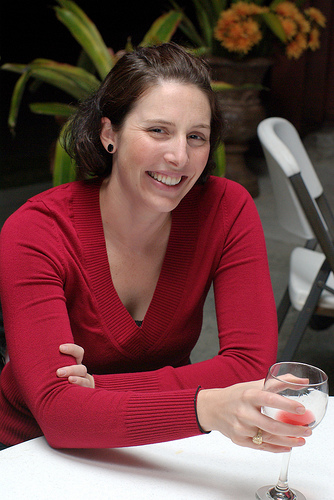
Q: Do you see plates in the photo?
A: No, there are no plates.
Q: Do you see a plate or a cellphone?
A: No, there are no plates or cell phones.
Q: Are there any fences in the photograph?
A: No, there are no fences.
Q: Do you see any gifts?
A: No, there are no gifts.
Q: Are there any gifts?
A: No, there are no gifts.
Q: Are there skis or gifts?
A: No, there are no gifts or skis.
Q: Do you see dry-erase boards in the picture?
A: No, there are no dry-erase boards.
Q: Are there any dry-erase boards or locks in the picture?
A: No, there are no dry-erase boards or locks.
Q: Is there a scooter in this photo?
A: No, there are no scooters.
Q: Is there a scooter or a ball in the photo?
A: No, there are no scooters or balls.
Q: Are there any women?
A: Yes, there is a woman.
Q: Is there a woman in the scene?
A: Yes, there is a woman.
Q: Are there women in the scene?
A: Yes, there is a woman.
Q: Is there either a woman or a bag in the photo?
A: Yes, there is a woman.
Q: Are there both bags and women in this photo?
A: No, there is a woman but no bags.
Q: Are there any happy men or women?
A: Yes, there is a happy woman.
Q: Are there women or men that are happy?
A: Yes, the woman is happy.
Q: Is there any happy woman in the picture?
A: Yes, there is a happy woman.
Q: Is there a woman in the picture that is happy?
A: Yes, there is a woman that is happy.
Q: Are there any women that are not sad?
A: Yes, there is a happy woman.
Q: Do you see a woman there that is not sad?
A: Yes, there is a happy woman.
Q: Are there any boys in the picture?
A: No, there are no boys.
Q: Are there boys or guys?
A: No, there are no boys or guys.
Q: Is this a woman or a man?
A: This is a woman.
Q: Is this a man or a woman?
A: This is a woman.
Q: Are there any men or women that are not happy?
A: No, there is a woman but she is happy.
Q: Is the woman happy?
A: Yes, the woman is happy.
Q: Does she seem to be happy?
A: Yes, the woman is happy.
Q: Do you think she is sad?
A: No, the woman is happy.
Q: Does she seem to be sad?
A: No, the woman is happy.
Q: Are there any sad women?
A: No, there is a woman but she is happy.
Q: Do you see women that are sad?
A: No, there is a woman but she is happy.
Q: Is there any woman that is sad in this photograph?
A: No, there is a woman but she is happy.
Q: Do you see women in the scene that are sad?
A: No, there is a woman but she is happy.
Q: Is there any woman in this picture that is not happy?
A: No, there is a woman but she is happy.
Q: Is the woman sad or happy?
A: The woman is happy.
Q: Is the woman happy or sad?
A: The woman is happy.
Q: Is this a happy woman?
A: Yes, this is a happy woman.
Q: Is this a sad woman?
A: No, this is a happy woman.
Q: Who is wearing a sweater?
A: The woman is wearing a sweater.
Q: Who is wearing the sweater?
A: The woman is wearing a sweater.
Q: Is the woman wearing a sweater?
A: Yes, the woman is wearing a sweater.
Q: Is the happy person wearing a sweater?
A: Yes, the woman is wearing a sweater.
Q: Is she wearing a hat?
A: No, the woman is wearing a sweater.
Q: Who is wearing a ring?
A: The woman is wearing a ring.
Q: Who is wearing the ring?
A: The woman is wearing a ring.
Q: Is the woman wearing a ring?
A: Yes, the woman is wearing a ring.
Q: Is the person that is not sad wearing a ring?
A: Yes, the woman is wearing a ring.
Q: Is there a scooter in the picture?
A: No, there are no scooters.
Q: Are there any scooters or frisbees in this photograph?
A: No, there are no scooters or frisbees.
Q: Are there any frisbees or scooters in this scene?
A: No, there are no scooters or frisbees.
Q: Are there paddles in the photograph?
A: No, there are no paddles.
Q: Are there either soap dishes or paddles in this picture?
A: No, there are no paddles or soap dishes.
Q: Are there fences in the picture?
A: No, there are no fences.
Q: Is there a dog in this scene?
A: No, there are no dogs.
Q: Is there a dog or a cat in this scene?
A: No, there are no dogs or cats.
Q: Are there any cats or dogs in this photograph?
A: No, there are no dogs or cats.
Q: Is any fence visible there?
A: No, there are no fences.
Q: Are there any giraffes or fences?
A: No, there are no fences or giraffes.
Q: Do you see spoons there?
A: No, there are no spoons.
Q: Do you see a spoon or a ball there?
A: No, there are no spoons or balls.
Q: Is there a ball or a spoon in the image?
A: No, there are no spoons or balls.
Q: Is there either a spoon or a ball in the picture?
A: No, there are no spoons or balls.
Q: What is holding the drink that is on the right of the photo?
A: The glass is holding the wine.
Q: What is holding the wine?
A: The glass is holding the wine.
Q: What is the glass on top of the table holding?
A: The glass is holding the wine.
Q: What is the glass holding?
A: The glass is holding the wine.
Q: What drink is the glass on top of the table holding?
A: The glass is holding the wine.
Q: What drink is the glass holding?
A: The glass is holding the wine.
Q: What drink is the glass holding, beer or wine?
A: The glass is holding wine.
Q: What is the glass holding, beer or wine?
A: The glass is holding wine.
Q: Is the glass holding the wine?
A: Yes, the glass is holding the wine.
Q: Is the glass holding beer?
A: No, the glass is holding the wine.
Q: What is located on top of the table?
A: The glass is on top of the table.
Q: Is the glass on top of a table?
A: Yes, the glass is on top of a table.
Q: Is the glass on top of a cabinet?
A: No, the glass is on top of a table.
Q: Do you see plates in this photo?
A: No, there are no plates.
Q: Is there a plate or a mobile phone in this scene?
A: No, there are no plates or cell phones.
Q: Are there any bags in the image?
A: No, there are no bags.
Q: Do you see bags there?
A: No, there are no bags.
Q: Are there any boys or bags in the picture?
A: No, there are no bags or boys.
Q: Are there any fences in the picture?
A: No, there are no fences.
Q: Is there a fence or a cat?
A: No, there are no fences or cats.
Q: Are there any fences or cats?
A: No, there are no fences or cats.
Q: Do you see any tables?
A: Yes, there is a table.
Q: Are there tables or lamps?
A: Yes, there is a table.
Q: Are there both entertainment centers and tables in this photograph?
A: No, there is a table but no entertainment centers.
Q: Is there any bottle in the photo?
A: No, there are no bottles.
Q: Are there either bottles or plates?
A: No, there are no bottles or plates.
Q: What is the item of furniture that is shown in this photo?
A: The piece of furniture is a table.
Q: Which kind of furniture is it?
A: The piece of furniture is a table.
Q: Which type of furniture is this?
A: This is a table.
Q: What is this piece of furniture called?
A: This is a table.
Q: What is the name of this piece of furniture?
A: This is a table.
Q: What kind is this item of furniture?
A: This is a table.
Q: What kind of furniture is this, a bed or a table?
A: This is a table.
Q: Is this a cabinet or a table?
A: This is a table.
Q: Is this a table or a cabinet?
A: This is a table.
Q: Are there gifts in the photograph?
A: No, there are no gifts.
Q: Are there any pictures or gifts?
A: No, there are no gifts or pictures.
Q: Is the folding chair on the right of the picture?
A: Yes, the folding chair is on the right of the image.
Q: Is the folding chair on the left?
A: No, the folding chair is on the right of the image.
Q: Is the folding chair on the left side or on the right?
A: The folding chair is on the right of the image.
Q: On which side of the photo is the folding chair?
A: The folding chair is on the right of the image.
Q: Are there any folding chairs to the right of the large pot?
A: Yes, there is a folding chair to the right of the pot.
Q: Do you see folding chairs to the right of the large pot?
A: Yes, there is a folding chair to the right of the pot.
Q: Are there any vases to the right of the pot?
A: No, there is a folding chair to the right of the pot.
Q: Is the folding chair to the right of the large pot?
A: Yes, the folding chair is to the right of the pot.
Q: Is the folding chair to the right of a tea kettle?
A: No, the folding chair is to the right of the pot.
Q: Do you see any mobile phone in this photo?
A: No, there are no cell phones.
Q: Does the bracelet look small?
A: Yes, the bracelet is small.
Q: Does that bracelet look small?
A: Yes, the bracelet is small.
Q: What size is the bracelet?
A: The bracelet is small.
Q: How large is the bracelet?
A: The bracelet is small.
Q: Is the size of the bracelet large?
A: No, the bracelet is small.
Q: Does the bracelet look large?
A: No, the bracelet is small.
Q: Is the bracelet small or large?
A: The bracelet is small.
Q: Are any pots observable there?
A: Yes, there is a pot.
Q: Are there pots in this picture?
A: Yes, there is a pot.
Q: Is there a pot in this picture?
A: Yes, there is a pot.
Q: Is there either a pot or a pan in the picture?
A: Yes, there is a pot.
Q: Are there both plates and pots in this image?
A: No, there is a pot but no plates.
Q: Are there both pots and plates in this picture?
A: No, there is a pot but no plates.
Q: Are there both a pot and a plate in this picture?
A: No, there is a pot but no plates.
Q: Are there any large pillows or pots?
A: Yes, there is a large pot.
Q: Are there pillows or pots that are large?
A: Yes, the pot is large.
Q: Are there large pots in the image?
A: Yes, there is a large pot.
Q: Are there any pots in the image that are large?
A: Yes, there is a pot that is large.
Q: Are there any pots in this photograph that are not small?
A: Yes, there is a large pot.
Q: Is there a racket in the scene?
A: No, there are no rackets.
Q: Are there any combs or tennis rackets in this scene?
A: No, there are no tennis rackets or combs.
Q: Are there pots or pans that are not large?
A: No, there is a pot but it is large.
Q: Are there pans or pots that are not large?
A: No, there is a pot but it is large.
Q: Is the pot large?
A: Yes, the pot is large.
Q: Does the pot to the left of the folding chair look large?
A: Yes, the pot is large.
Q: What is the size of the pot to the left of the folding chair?
A: The pot is large.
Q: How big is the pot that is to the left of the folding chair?
A: The pot is large.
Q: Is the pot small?
A: No, the pot is large.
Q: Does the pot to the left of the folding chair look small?
A: No, the pot is large.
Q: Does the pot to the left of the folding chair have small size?
A: No, the pot is large.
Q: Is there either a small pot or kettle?
A: No, there is a pot but it is large.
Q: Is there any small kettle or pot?
A: No, there is a pot but it is large.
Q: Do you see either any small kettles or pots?
A: No, there is a pot but it is large.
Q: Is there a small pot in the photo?
A: No, there is a pot but it is large.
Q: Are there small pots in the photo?
A: No, there is a pot but it is large.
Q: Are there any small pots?
A: No, there is a pot but it is large.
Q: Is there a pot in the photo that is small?
A: No, there is a pot but it is large.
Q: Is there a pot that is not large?
A: No, there is a pot but it is large.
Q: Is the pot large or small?
A: The pot is large.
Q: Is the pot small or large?
A: The pot is large.